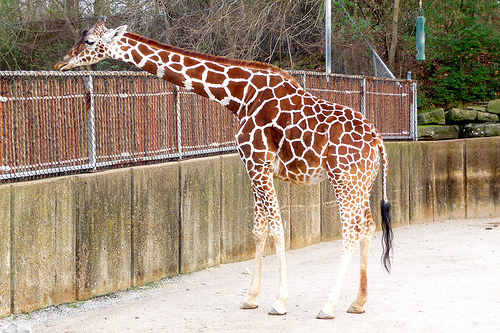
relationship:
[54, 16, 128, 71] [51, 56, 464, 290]
giraffe's head of giraffe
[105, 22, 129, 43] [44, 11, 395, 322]
ear of animal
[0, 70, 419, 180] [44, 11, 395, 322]
fence in front animal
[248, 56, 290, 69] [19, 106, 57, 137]
branches of tree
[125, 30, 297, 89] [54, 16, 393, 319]
hair on animal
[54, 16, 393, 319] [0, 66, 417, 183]
animal next to fence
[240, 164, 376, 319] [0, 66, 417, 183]
giraffe's legs behind fence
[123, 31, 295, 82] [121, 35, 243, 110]
hair along giraffe's neck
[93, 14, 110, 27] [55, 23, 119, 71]
ossicones on top of giraffe's head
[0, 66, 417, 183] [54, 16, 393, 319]
fence near animal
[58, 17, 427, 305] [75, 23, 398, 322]
spot on giraffe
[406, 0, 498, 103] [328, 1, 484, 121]
leaves on background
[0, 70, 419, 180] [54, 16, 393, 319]
fence next to animal